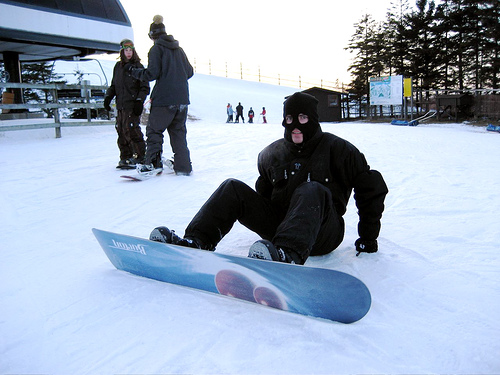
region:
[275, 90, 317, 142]
Black ski mask on man's head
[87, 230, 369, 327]
Long snowboard on man's feet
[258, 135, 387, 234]
Black winter jacket on man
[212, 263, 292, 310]
Image of planets on snowboard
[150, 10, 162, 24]
Yellow pom pom on man's hat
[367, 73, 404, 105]
White sign on fence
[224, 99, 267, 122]
Group of people standing in snow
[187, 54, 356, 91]
Fence at edge of ski area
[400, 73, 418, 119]
Yellow sign on posts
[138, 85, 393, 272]
person at a ski slope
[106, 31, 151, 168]
person at a ski slope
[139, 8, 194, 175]
person at a ski slope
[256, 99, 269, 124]
person at a ski slope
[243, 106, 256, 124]
person at a ski slope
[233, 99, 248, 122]
person at a ski slope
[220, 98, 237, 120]
person at a ski slope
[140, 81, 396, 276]
person wearing winter clothes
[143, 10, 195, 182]
person wearing winter clothes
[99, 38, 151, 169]
person wearing winter clothes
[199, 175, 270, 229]
leg of a person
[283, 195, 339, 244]
leg of a person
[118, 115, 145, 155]
leg of a person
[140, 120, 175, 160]
leg of a person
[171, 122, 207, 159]
leg of a person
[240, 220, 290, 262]
feet of a person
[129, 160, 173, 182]
feet of a person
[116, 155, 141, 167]
feet of a person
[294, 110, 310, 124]
eye of a person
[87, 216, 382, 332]
THE MAN HAS A SNOW BOARD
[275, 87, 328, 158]
THE MAN IS WEARING A SKI MASK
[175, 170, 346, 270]
THE MAN IS WEARING BLACK PANTS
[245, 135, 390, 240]
THE MAN IS WEARING A BLACK JACKET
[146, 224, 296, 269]
THE MAN IS WEARING BLACK BOOTS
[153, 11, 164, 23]
THE GUY HAS A POMPOM ON HIS HAT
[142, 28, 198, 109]
THE GUY IS WEARING A GREY JACKET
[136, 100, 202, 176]
THE GUY IS WEARING GREY PANTS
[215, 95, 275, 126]
THE GROUP OF PEOPLE ARE IN THE DISTANCE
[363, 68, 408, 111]
THIS IS A SIGN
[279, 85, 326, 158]
head of a person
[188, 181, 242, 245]
leg of a person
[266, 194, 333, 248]
leg of a person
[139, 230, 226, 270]
feet of a person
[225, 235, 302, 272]
feet of a person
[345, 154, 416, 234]
arm of a person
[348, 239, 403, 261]
hand of a person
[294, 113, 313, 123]
eye of a person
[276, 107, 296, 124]
eye of a person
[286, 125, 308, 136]
mouth of a person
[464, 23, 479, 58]
green leaves on the tree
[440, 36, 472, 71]
green leaves on the tree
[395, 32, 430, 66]
green leaves on the tree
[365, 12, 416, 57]
green leaves on the tree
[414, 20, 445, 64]
green leaves on the tree